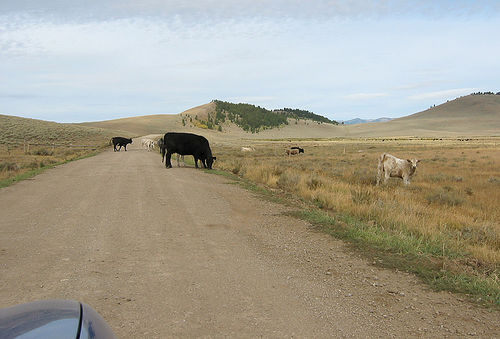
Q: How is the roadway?
A: Dirt.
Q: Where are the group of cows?
A: Countryside.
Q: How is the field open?
A: Wide.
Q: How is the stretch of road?
A: Long.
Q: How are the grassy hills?
A: Large.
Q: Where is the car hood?
A: On the road, far left.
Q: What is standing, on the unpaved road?
A: A number of black and white cows.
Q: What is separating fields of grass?
A: A dirt road.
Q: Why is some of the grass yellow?
A: It is dehydrated, from lack of moisture.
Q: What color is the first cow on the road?
A: Black.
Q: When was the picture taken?
A: Daytime.